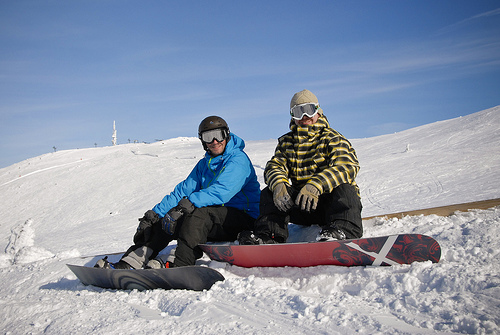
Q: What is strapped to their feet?
A: Snowboards.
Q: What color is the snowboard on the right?
A: Red and black.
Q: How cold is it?
A: Very.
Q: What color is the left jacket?
A: Blue.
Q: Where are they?
A: On a mountain.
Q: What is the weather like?
A: Sunny.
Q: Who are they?
A: 2 men.